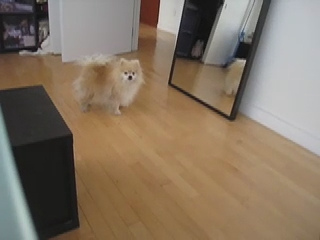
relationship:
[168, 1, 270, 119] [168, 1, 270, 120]
mirror has frame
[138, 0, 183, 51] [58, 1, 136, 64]
hall next to door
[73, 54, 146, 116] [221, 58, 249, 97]
dog has a reflection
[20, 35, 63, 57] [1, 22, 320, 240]
cloth on floor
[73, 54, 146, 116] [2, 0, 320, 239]
dog in room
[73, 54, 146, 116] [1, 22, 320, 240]
dog on floor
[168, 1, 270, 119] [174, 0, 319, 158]
mirror against wall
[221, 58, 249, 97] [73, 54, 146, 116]
reflection of dog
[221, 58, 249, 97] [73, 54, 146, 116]
reflection of pomeranian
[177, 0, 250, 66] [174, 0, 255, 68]
reflection of closet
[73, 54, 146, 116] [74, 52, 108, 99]
dog has a tail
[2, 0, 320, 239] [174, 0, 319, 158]
room has wall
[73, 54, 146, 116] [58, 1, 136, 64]
dog by door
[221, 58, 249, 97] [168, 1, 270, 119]
reflection in mirror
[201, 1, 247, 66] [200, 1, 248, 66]
reflection of door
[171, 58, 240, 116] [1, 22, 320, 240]
reflection of flooring